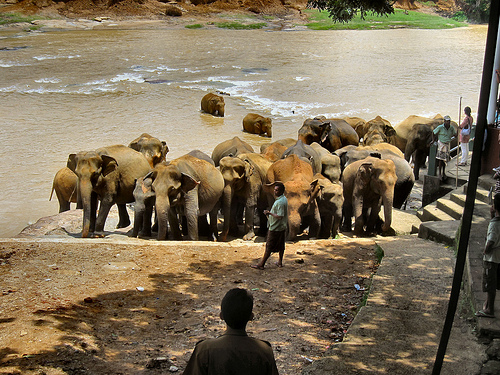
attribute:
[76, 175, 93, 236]
trunk — brown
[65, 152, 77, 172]
ear — big, floppy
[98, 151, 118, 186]
ear — big, floppy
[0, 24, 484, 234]
river — muddy colored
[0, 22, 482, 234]
water — murky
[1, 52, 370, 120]
river rapid — mild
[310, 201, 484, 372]
walkway — cement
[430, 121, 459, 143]
shirt — teal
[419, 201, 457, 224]
step — cement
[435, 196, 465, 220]
step — cement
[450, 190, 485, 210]
step — cement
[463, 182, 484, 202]
step — cement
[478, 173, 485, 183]
step — cement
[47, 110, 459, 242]
group — large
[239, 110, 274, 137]
elephant — brown 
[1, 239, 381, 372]
ground — muddy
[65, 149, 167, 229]
elephant — large 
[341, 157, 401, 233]
elephant — brown 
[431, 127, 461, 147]
shirt — green 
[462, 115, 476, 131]
shirt — pink 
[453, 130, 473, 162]
pants — white 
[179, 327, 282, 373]
shirt — brown 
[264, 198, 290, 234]
shirt — white 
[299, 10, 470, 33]
area — grassy 